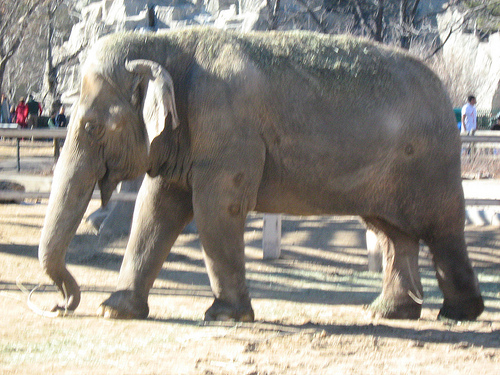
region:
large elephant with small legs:
[69, 57, 497, 293]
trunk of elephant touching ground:
[27, 176, 95, 332]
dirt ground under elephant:
[48, 250, 399, 374]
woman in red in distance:
[12, 79, 57, 153]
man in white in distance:
[462, 80, 494, 150]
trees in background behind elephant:
[339, 10, 452, 35]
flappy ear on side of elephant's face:
[119, 82, 209, 156]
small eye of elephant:
[72, 112, 102, 142]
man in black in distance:
[16, 82, 48, 120]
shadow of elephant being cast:
[246, 296, 490, 361]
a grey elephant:
[30, 23, 480, 348]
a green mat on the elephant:
[117, 24, 389, 76]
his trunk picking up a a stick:
[12, 255, 112, 323]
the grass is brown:
[0, 203, 495, 370]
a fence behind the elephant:
[4, 123, 489, 184]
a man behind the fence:
[457, 94, 479, 139]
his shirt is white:
[462, 102, 479, 136]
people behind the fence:
[10, 90, 45, 127]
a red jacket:
[10, 99, 29, 120]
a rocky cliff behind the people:
[2, 0, 498, 113]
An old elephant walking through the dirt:
[42, 23, 484, 336]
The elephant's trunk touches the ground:
[31, 123, 121, 323]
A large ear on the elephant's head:
[127, 49, 185, 147]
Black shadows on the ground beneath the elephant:
[167, 205, 378, 302]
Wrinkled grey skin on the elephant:
[157, 137, 229, 187]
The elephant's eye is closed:
[78, 115, 104, 143]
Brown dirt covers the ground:
[45, 320, 203, 368]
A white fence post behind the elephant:
[259, 210, 296, 265]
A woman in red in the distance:
[15, 100, 33, 125]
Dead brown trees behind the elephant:
[2, 2, 67, 99]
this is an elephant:
[41, 23, 453, 327]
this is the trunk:
[33, 172, 98, 303]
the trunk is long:
[28, 170, 99, 310]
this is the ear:
[128, 47, 177, 141]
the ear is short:
[128, 55, 175, 150]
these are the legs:
[101, 194, 260, 333]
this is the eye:
[83, 117, 98, 142]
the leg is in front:
[100, 195, 183, 312]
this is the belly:
[285, 57, 398, 196]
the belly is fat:
[286, 89, 372, 192]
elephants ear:
[131, 65, 186, 142]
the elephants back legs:
[375, 223, 475, 328]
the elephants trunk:
[37, 160, 102, 316]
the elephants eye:
[82, 122, 102, 139]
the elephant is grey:
[21, 28, 492, 340]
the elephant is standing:
[30, 20, 487, 352]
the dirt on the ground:
[47, 325, 225, 367]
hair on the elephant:
[270, 37, 353, 70]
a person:
[462, 93, 480, 130]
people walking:
[6, 92, 46, 128]